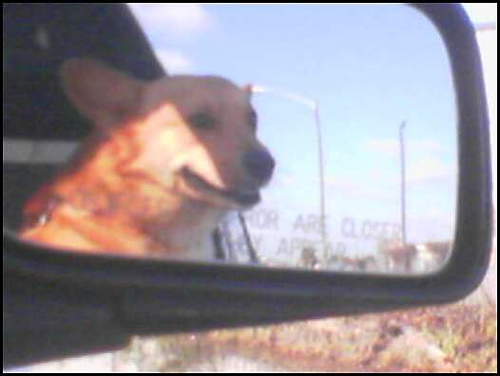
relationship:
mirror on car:
[0, 3, 494, 329] [6, 21, 484, 357]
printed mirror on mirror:
[21, 175, 408, 274] [14, 0, 464, 294]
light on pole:
[387, 111, 416, 248] [308, 101, 420, 262]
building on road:
[347, 237, 447, 271] [234, 350, 426, 372]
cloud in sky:
[128, 1, 206, 74] [151, 5, 458, 152]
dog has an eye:
[7, 51, 288, 256] [179, 107, 220, 131]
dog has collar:
[7, 51, 288, 256] [21, 183, 118, 244]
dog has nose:
[7, 51, 288, 256] [242, 144, 274, 181]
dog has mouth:
[7, 51, 288, 256] [180, 166, 267, 206]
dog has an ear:
[7, 51, 288, 256] [54, 53, 145, 128]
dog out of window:
[7, 51, 288, 256] [2, 3, 221, 262]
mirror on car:
[0, 3, 494, 329] [0, 3, 499, 373]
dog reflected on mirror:
[7, 51, 288, 256] [0, 3, 494, 329]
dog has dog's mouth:
[7, 51, 288, 256] [172, 160, 266, 212]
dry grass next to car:
[218, 304, 496, 371] [0, 3, 499, 373]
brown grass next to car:
[149, 304, 497, 371] [0, 3, 499, 373]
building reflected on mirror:
[347, 237, 447, 271] [0, 3, 494, 329]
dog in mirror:
[25, 51, 287, 260] [0, 3, 494, 329]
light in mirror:
[397, 111, 411, 248] [0, 3, 494, 329]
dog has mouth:
[7, 51, 288, 256] [176, 162, 262, 211]